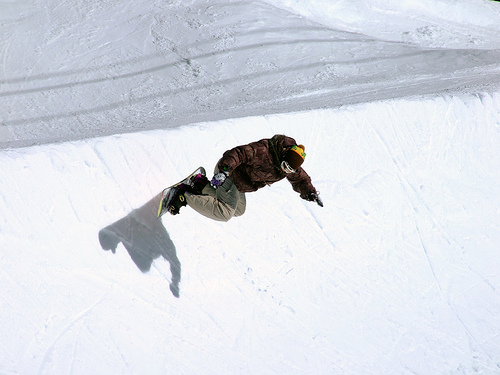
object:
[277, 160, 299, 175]
goggles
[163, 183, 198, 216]
sneakers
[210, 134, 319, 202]
coat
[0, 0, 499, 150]
shadow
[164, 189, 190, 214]
feet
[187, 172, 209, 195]
feet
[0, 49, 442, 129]
lines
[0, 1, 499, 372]
ground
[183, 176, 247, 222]
pants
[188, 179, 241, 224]
legs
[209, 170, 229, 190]
glove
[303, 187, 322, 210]
glove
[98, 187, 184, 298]
shadow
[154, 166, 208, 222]
board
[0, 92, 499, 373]
slope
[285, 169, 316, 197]
arm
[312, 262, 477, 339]
white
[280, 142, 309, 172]
cap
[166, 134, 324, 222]
man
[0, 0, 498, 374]
snow